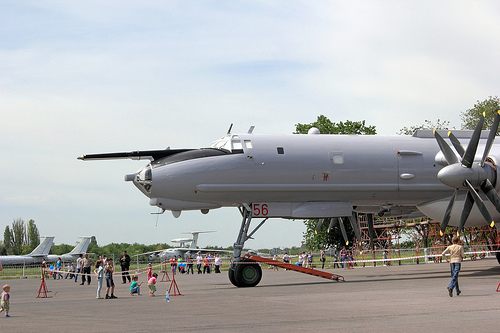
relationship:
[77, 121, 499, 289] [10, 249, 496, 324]
airplane on ground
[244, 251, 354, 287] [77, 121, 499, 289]
ladder to airplane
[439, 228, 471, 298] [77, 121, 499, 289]
person near airplane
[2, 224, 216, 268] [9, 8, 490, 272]
planes in background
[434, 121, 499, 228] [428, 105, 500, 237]
propeller on wings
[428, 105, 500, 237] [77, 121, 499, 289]
wings on airplane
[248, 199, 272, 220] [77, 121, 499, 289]
numbers on airplane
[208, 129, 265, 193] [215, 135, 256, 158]
cockpit has windows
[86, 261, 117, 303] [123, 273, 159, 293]
people watching chidren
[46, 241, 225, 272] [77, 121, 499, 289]
people examing airplane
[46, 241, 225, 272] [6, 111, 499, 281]
people around airplanes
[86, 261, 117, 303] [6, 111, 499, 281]
people watching airplanes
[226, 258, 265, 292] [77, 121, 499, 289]
wheels on airplane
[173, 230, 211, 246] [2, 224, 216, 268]
tail on planes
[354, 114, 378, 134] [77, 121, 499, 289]
antenna on airplane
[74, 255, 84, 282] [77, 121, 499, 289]
man near airplane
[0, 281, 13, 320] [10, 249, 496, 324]
baby on ground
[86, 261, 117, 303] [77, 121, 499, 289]
people watching airplane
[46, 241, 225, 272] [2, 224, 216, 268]
people watching planes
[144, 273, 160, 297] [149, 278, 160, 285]
chidren wearing pink shirt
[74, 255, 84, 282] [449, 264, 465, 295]
man wearing jeans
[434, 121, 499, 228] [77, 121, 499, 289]
propeller on airplane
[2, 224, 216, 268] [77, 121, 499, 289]
planes near airplane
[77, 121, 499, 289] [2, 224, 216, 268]
airplane near planes